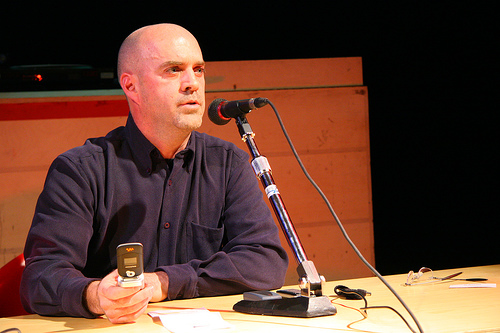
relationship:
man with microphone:
[20, 22, 289, 325] [207, 96, 270, 126]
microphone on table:
[207, 96, 270, 126] [1, 265, 498, 333]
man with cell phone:
[20, 22, 289, 325] [115, 241, 146, 289]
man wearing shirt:
[20, 22, 289, 325] [19, 113, 289, 319]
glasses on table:
[403, 266, 464, 288] [1, 265, 498, 333]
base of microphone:
[234, 294, 338, 319] [207, 96, 270, 126]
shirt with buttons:
[19, 113, 289, 319] [163, 178, 173, 231]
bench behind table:
[0, 56, 377, 286] [1, 265, 498, 333]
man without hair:
[20, 22, 289, 325] [114, 22, 207, 132]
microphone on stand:
[205, 95, 272, 126] [231, 100, 336, 319]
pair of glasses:
[403, 267, 466, 286] [403, 266, 464, 288]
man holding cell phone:
[20, 22, 289, 325] [115, 241, 146, 289]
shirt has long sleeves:
[19, 113, 289, 319] [19, 154, 290, 320]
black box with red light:
[0, 62, 118, 92] [22, 71, 46, 81]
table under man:
[1, 265, 498, 333] [20, 22, 289, 325]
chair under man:
[0, 254, 33, 320] [20, 22, 289, 325]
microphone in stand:
[205, 95, 272, 126] [231, 100, 336, 319]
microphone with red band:
[205, 95, 272, 126] [217, 100, 232, 123]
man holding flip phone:
[20, 22, 289, 325] [115, 241, 146, 289]